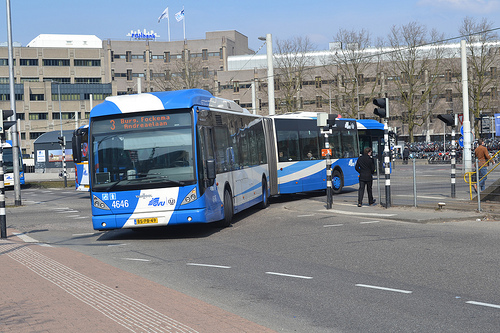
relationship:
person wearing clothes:
[345, 148, 384, 216] [356, 157, 386, 209]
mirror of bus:
[200, 154, 220, 188] [96, 99, 313, 238]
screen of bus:
[89, 114, 202, 198] [96, 99, 313, 238]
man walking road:
[345, 148, 384, 216] [0, 159, 500, 333]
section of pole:
[8, 13, 28, 210] [4, 3, 21, 208]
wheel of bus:
[216, 191, 243, 222] [96, 99, 313, 238]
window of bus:
[89, 114, 202, 198] [96, 99, 313, 238]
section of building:
[0, 44, 114, 104] [0, 35, 123, 95]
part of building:
[0, 42, 118, 92] [0, 35, 123, 95]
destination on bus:
[87, 108, 189, 139] [96, 99, 313, 238]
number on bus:
[109, 197, 134, 210] [96, 99, 313, 238]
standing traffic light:
[374, 92, 394, 130] [366, 93, 399, 131]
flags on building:
[153, 6, 193, 45] [0, 35, 123, 95]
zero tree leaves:
[270, 15, 453, 90] [267, 27, 437, 93]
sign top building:
[128, 27, 159, 42] [0, 35, 123, 95]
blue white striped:
[87, 188, 209, 226] [79, 180, 207, 229]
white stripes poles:
[461, 39, 474, 181] [443, 124, 462, 199]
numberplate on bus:
[133, 217, 159, 226] [96, 99, 313, 238]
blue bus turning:
[87, 188, 209, 226] [96, 99, 313, 238]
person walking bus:
[345, 148, 384, 216] [96, 99, 313, 238]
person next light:
[345, 148, 384, 216] [366, 93, 399, 131]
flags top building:
[153, 6, 193, 45] [0, 35, 123, 95]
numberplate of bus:
[127, 213, 176, 235] [96, 99, 313, 238]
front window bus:
[89, 114, 202, 198] [96, 99, 313, 238]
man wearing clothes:
[345, 148, 384, 216] [355, 154, 375, 181]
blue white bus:
[87, 188, 209, 226] [96, 99, 313, 238]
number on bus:
[106, 118, 117, 134] [96, 99, 313, 238]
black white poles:
[377, 129, 392, 136] [443, 124, 462, 199]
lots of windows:
[0, 52, 98, 76] [5, 58, 98, 101]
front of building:
[101, 36, 229, 85] [0, 35, 123, 95]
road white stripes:
[158, 247, 350, 304] [178, 261, 317, 284]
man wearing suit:
[345, 148, 384, 216] [354, 151, 378, 211]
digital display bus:
[99, 110, 197, 139] [96, 99, 313, 238]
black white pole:
[377, 129, 392, 136] [4, 3, 21, 208]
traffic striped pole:
[367, 94, 394, 120] [4, 3, 21, 208]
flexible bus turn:
[247, 112, 312, 215] [66, 85, 412, 244]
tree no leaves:
[334, 44, 438, 95] [267, 27, 437, 93]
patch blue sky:
[209, 13, 323, 42] [278, 5, 349, 37]